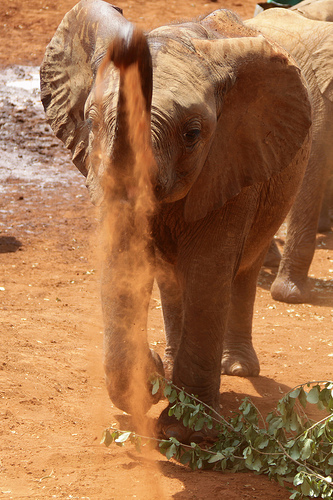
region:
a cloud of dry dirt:
[93, 65, 168, 457]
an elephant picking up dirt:
[30, 0, 313, 442]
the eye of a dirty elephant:
[180, 116, 200, 143]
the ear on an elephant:
[183, 19, 310, 241]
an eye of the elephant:
[83, 107, 104, 135]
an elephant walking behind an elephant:
[241, 1, 329, 308]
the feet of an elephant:
[92, 339, 288, 446]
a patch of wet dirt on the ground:
[0, 61, 83, 232]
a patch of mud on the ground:
[0, 57, 88, 235]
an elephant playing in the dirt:
[35, 3, 318, 444]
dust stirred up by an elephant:
[82, 58, 183, 494]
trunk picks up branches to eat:
[96, 329, 329, 499]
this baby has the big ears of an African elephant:
[33, 0, 312, 223]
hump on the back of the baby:
[168, 2, 267, 45]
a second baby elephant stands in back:
[243, 4, 332, 297]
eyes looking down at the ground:
[82, 104, 213, 156]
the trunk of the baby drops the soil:
[71, 33, 172, 295]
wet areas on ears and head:
[60, 0, 212, 57]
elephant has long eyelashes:
[72, 104, 104, 137]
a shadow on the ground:
[0, 227, 26, 258]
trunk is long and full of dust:
[99, 121, 168, 410]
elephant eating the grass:
[104, 397, 311, 464]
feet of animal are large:
[160, 415, 228, 451]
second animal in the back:
[276, 80, 327, 310]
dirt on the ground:
[16, 366, 110, 497]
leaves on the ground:
[190, 407, 327, 498]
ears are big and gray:
[209, 48, 311, 231]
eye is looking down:
[179, 107, 200, 157]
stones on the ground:
[271, 310, 327, 328]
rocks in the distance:
[0, 78, 78, 185]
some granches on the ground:
[118, 382, 328, 480]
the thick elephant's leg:
[85, 168, 165, 409]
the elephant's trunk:
[111, 36, 150, 195]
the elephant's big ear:
[192, 39, 309, 209]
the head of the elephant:
[43, 26, 307, 213]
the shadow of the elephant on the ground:
[168, 383, 324, 499]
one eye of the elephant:
[183, 119, 202, 140]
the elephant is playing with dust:
[33, 4, 313, 453]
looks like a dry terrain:
[4, 311, 70, 497]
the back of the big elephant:
[162, 16, 225, 35]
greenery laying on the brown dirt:
[140, 370, 326, 494]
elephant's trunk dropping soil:
[87, 24, 165, 470]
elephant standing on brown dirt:
[36, 1, 323, 425]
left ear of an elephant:
[192, 36, 311, 215]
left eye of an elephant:
[180, 119, 209, 147]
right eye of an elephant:
[81, 105, 108, 136]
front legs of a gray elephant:
[99, 236, 228, 441]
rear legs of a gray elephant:
[146, 256, 267, 383]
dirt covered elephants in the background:
[256, 0, 328, 311]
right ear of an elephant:
[41, 5, 90, 177]